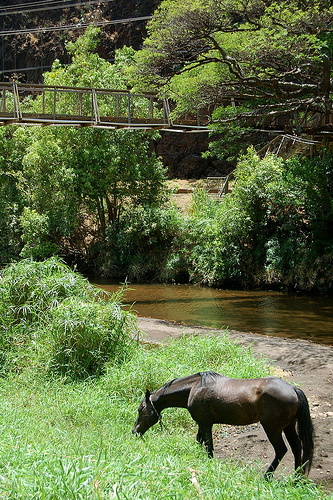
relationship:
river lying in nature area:
[129, 284, 331, 347] [26, 138, 331, 487]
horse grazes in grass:
[129, 366, 315, 488] [16, 354, 174, 498]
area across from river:
[140, 138, 215, 190] [129, 284, 331, 347]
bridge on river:
[0, 80, 201, 133] [129, 284, 331, 347]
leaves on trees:
[173, 68, 214, 105] [150, 10, 331, 141]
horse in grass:
[129, 366, 315, 488] [4, 373, 116, 492]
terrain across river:
[2, 177, 332, 230] [129, 284, 331, 347]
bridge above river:
[41, 66, 256, 143] [129, 284, 331, 347]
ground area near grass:
[136, 317, 331, 483] [2, 318, 318, 499]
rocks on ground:
[236, 430, 331, 479] [5, 341, 331, 497]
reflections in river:
[121, 294, 331, 346] [129, 284, 331, 347]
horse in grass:
[129, 366, 315, 488] [0, 356, 176, 498]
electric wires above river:
[2, 0, 162, 76] [129, 284, 331, 347]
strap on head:
[146, 392, 169, 431] [132, 389, 162, 437]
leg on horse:
[261, 422, 288, 480] [129, 366, 315, 488]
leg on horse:
[191, 413, 213, 460] [129, 366, 315, 488]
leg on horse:
[282, 424, 305, 475] [132, 367, 316, 478]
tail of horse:
[293, 385, 315, 478] [129, 366, 315, 488]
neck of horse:
[153, 373, 189, 409] [129, 366, 315, 488]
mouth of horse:
[131, 424, 145, 436] [129, 366, 315, 488]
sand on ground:
[119, 315, 331, 499] [117, 315, 316, 491]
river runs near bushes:
[96, 282, 331, 347] [3, 123, 331, 288]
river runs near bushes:
[96, 282, 331, 347] [1, 259, 143, 379]